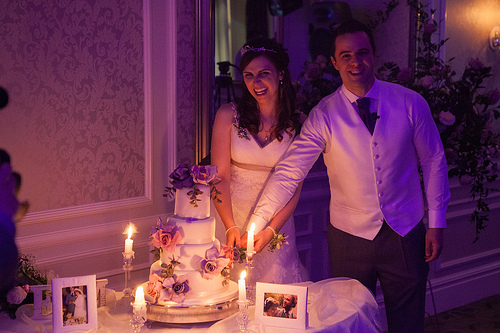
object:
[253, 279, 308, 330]
picture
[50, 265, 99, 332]
picture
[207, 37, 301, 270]
bride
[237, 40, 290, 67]
tiara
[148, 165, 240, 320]
cake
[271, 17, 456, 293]
groom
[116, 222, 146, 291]
candle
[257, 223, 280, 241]
wrist band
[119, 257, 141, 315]
candle stick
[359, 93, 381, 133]
black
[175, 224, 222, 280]
frosting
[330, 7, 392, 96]
head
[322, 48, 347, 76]
ear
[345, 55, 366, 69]
nose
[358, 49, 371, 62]
eyes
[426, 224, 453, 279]
hand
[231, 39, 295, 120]
head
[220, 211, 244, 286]
hand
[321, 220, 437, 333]
pants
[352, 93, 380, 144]
tie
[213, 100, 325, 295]
wedding dress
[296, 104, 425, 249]
vest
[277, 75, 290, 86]
earring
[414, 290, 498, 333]
carpet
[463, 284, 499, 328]
part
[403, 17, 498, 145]
mirror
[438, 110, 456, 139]
flower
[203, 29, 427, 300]
couple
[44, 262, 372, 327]
table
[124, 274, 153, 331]
candles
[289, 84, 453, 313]
suit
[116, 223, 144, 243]
flame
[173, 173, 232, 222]
top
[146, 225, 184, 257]
rose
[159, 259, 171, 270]
leaves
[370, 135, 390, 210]
buttons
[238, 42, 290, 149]
hair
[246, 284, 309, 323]
frame